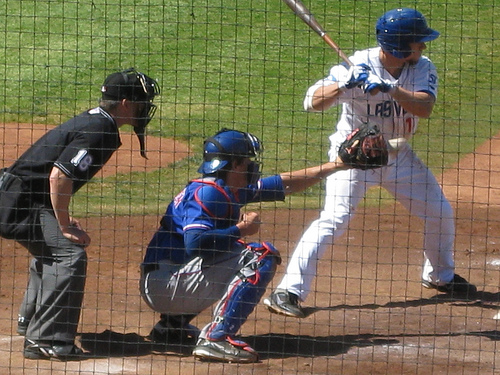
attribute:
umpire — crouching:
[3, 53, 159, 374]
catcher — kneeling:
[169, 101, 283, 345]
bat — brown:
[275, 0, 386, 103]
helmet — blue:
[379, 5, 441, 69]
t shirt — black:
[34, 112, 105, 188]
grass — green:
[2, 4, 62, 55]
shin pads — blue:
[240, 285, 252, 326]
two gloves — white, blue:
[333, 60, 396, 97]